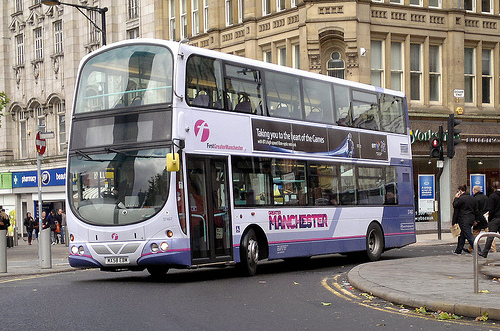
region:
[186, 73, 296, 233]
the bus is a double decker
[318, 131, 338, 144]
the sign is black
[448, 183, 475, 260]
the lady is walking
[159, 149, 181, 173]
the mirror cover is yellow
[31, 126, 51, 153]
the sign is red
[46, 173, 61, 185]
the sign is blue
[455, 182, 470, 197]
she is holding the phone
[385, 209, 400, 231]
the bus is purple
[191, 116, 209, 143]
the logo is pink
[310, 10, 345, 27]
the building is tan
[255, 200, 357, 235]
MANCHESTER can be read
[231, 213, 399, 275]
bus with 2 tires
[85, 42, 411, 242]
large double-decker bus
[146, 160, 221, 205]
bus with yellow mirror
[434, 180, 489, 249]
woman talking on cellphone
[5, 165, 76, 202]
blue banner with white words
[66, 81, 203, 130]
bus has green object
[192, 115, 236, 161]
red and white symbol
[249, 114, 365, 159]
advertisment with white words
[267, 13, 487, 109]
large brown building in back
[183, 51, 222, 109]
glass window on bus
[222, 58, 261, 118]
glass window on bus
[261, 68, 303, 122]
glass window on bus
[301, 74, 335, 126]
glass window on bus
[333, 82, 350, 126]
glass window on bus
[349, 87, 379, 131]
glass window on bus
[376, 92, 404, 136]
glass window on bus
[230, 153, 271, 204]
glass window on bus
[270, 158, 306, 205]
glass window on bus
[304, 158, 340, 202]
glass window on bus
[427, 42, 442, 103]
window on large building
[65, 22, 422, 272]
the bus is a double decker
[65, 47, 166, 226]
the front windows are tinted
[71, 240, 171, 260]
the head lights are turned on